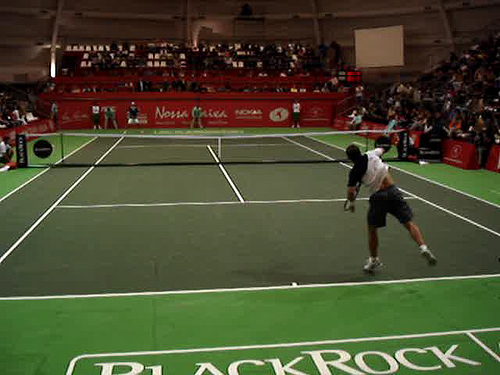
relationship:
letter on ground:
[191, 361, 223, 374] [8, 158, 496, 371]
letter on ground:
[293, 335, 348, 373] [1, 123, 499, 373]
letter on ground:
[93, 357, 144, 373] [1, 123, 499, 373]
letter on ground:
[424, 338, 486, 373] [1, 123, 499, 373]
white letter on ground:
[227, 359, 265, 374] [3, 255, 498, 372]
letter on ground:
[263, 354, 309, 375] [1, 123, 499, 373]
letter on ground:
[299, 349, 365, 375] [1, 123, 499, 373]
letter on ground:
[353, 349, 399, 374] [1, 123, 499, 373]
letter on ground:
[93, 361, 146, 372] [1, 123, 499, 373]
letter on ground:
[147, 362, 170, 372] [1, 123, 499, 373]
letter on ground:
[188, 356, 218, 372] [1, 123, 499, 373]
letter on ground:
[265, 354, 301, 372] [1, 123, 499, 373]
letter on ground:
[353, 349, 393, 372] [1, 123, 499, 373]